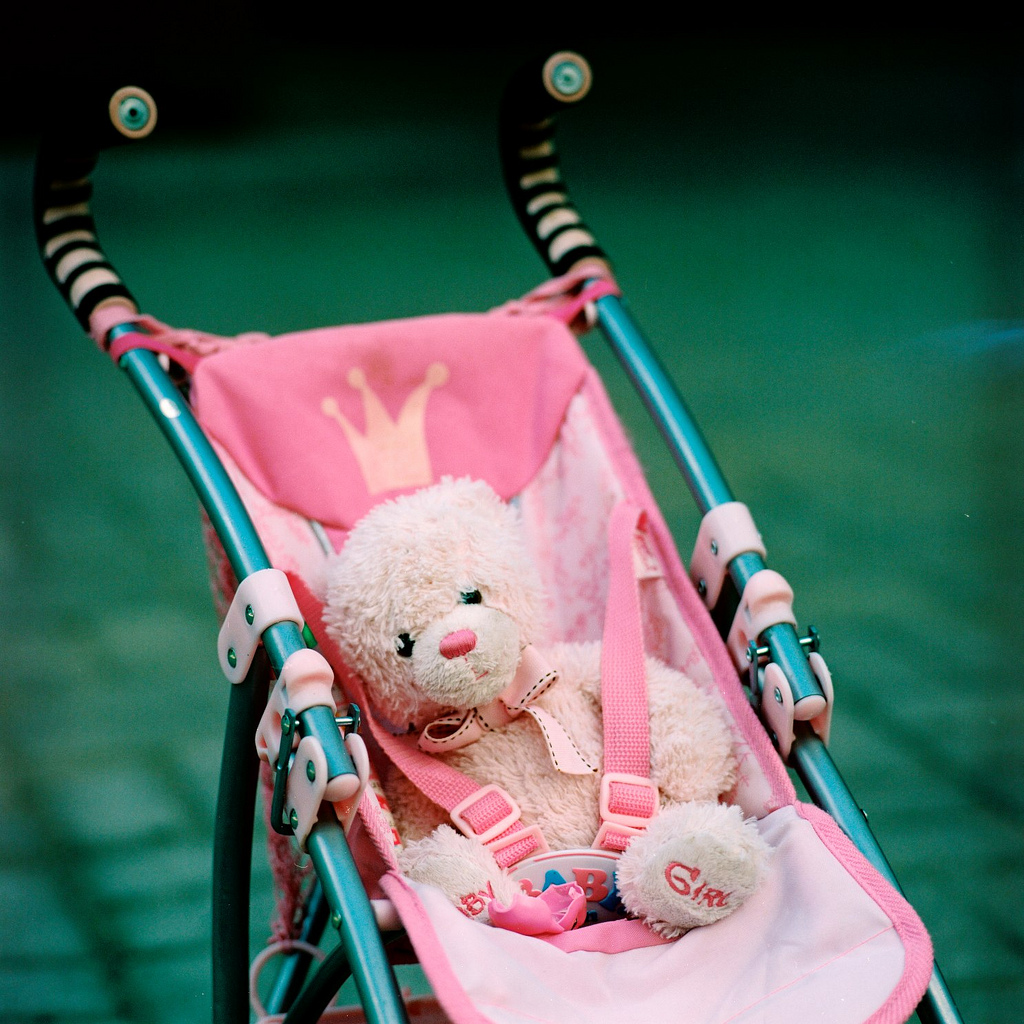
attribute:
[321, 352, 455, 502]
crown pattern — orange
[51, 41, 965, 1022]
stroller — FOR SMALL CHILD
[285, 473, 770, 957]
bear — pink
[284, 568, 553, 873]
strap — pink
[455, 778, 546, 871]
buckle — plastic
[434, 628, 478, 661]
nose — pink, threaded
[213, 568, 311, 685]
clamp — pink, plastic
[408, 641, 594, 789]
ribbon — pink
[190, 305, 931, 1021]
cloth — pink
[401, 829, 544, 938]
foot — pink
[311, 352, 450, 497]
crown — gold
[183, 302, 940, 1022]
fabric — pink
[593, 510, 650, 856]
straps — SAFETY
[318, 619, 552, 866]
straps — SAFETY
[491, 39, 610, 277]
handle — BLACK, PINK, STROLLER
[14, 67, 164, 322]
handle — BLACK, PINK, STROLLER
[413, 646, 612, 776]
bow — PINK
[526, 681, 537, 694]
dots — BLACK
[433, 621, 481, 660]
nose — PINK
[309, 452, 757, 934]
teddy bear — SHAGGY, PINK, WOOLY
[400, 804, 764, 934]
feet — BEAR'S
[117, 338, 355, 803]
bars — GREEN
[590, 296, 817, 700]
bars — GREEN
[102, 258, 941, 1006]
seat — PINK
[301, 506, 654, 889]
straps — PINK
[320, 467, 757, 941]
bear — TEDDY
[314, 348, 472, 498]
design — PINK, ORANGISH, CROWN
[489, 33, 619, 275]
handle — BLACK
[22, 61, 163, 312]
handle — BLACK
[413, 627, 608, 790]
bow — LITTLE, PINK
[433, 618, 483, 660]
nose — BRIGHT PINK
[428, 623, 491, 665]
nose — PINK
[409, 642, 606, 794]
ribbon — PINK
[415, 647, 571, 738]
neck — BEAR'S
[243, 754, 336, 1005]
chain — PINK, FUZZY, KEY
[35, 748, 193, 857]
squares — GREEN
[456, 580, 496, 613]
button — BLACK